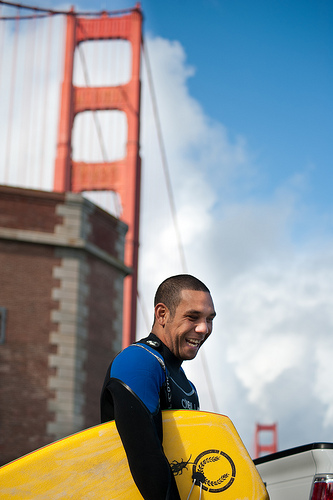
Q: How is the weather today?
A: It is clear.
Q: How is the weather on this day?
A: It is clear.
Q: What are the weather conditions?
A: It is clear.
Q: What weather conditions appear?
A: It is clear.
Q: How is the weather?
A: It is clear.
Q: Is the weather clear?
A: Yes, it is clear.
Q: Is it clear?
A: Yes, it is clear.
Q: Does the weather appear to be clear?
A: Yes, it is clear.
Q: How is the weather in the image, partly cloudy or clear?
A: It is clear.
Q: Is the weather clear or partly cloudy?
A: It is clear.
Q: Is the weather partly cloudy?
A: No, it is clear.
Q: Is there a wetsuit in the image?
A: Yes, there is a wetsuit.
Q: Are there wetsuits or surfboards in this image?
A: Yes, there is a wetsuit.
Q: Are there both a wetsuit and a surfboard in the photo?
A: Yes, there are both a wetsuit and a surfboard.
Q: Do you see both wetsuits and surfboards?
A: Yes, there are both a wetsuit and a surfboard.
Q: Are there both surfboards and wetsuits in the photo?
A: Yes, there are both a wetsuit and a surfboard.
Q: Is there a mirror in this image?
A: No, there are no mirrors.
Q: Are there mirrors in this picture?
A: No, there are no mirrors.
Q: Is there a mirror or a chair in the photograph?
A: No, there are no mirrors or chairs.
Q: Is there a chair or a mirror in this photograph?
A: No, there are no mirrors or chairs.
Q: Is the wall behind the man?
A: Yes, the wall is behind the man.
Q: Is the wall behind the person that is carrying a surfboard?
A: Yes, the wall is behind the man.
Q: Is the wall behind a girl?
A: No, the wall is behind the man.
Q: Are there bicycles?
A: No, there are no bicycles.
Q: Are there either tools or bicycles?
A: No, there are no bicycles or tools.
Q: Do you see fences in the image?
A: No, there are no fences.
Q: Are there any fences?
A: No, there are no fences.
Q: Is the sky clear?
A: Yes, the sky is clear.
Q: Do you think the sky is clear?
A: Yes, the sky is clear.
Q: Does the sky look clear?
A: Yes, the sky is clear.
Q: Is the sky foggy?
A: No, the sky is clear.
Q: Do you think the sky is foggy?
A: No, the sky is clear.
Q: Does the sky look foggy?
A: No, the sky is clear.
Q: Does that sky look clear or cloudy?
A: The sky is clear.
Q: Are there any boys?
A: No, there are no boys.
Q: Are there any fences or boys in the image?
A: No, there are no boys or fences.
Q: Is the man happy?
A: Yes, the man is happy.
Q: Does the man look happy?
A: Yes, the man is happy.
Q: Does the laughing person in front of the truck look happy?
A: Yes, the man is happy.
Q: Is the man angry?
A: No, the man is happy.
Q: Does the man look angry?
A: No, the man is happy.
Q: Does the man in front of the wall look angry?
A: No, the man is happy.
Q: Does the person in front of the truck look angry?
A: No, the man is happy.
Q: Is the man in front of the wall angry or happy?
A: The man is happy.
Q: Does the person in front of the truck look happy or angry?
A: The man is happy.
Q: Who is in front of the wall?
A: The man is in front of the wall.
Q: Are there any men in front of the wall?
A: Yes, there is a man in front of the wall.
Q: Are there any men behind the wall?
A: No, the man is in front of the wall.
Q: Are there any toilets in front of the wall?
A: No, there is a man in front of the wall.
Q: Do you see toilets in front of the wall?
A: No, there is a man in front of the wall.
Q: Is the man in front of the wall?
A: Yes, the man is in front of the wall.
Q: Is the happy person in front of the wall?
A: Yes, the man is in front of the wall.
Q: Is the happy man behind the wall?
A: No, the man is in front of the wall.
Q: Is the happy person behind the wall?
A: No, the man is in front of the wall.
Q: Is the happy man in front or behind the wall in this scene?
A: The man is in front of the wall.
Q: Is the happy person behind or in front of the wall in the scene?
A: The man is in front of the wall.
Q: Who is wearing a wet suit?
A: The man is wearing a wet suit.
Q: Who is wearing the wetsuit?
A: The man is wearing a wet suit.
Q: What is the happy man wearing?
A: The man is wearing a wetsuit.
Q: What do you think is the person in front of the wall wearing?
A: The man is wearing a wetsuit.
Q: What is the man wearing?
A: The man is wearing a wetsuit.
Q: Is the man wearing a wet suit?
A: Yes, the man is wearing a wet suit.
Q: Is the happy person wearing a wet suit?
A: Yes, the man is wearing a wet suit.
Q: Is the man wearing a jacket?
A: No, the man is wearing a wet suit.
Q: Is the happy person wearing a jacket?
A: No, the man is wearing a wet suit.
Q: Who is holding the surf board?
A: The man is holding the surf board.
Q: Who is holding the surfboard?
A: The man is holding the surf board.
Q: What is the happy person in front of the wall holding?
A: The man is holding the surfboard.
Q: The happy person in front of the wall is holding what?
A: The man is holding the surfboard.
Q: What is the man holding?
A: The man is holding the surfboard.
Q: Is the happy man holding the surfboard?
A: Yes, the man is holding the surfboard.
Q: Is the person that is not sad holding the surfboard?
A: Yes, the man is holding the surfboard.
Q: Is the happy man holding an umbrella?
A: No, the man is holding the surfboard.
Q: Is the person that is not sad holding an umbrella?
A: No, the man is holding the surfboard.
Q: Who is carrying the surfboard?
A: The man is carrying the surfboard.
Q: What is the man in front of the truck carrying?
A: The man is carrying a surf board.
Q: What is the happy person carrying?
A: The man is carrying a surf board.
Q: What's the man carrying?
A: The man is carrying a surf board.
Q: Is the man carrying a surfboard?
A: Yes, the man is carrying a surfboard.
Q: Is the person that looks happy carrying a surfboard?
A: Yes, the man is carrying a surfboard.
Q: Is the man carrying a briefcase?
A: No, the man is carrying a surfboard.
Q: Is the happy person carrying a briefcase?
A: No, the man is carrying a surfboard.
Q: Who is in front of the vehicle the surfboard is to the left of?
A: The man is in front of the truck.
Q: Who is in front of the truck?
A: The man is in front of the truck.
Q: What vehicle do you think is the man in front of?
A: The man is in front of the truck.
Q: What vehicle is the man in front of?
A: The man is in front of the truck.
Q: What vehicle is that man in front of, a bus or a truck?
A: The man is in front of a truck.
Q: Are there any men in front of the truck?
A: Yes, there is a man in front of the truck.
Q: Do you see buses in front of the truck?
A: No, there is a man in front of the truck.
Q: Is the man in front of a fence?
A: No, the man is in front of the truck.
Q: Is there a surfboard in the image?
A: Yes, there is a surfboard.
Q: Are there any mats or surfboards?
A: Yes, there is a surfboard.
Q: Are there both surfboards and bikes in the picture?
A: No, there is a surfboard but no bikes.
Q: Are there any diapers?
A: No, there are no diapers.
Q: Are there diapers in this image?
A: No, there are no diapers.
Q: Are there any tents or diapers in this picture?
A: No, there are no diapers or tents.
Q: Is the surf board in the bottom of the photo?
A: Yes, the surf board is in the bottom of the image.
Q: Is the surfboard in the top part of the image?
A: No, the surfboard is in the bottom of the image.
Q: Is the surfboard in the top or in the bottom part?
A: The surfboard is in the bottom of the image.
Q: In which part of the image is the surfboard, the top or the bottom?
A: The surfboard is in the bottom of the image.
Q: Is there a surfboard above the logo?
A: Yes, there is a surfboard above the logo.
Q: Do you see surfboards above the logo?
A: Yes, there is a surfboard above the logo.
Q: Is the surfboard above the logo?
A: Yes, the surfboard is above the logo.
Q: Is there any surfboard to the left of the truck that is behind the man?
A: Yes, there is a surfboard to the left of the truck.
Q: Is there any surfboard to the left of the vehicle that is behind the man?
A: Yes, there is a surfboard to the left of the truck.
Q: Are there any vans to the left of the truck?
A: No, there is a surfboard to the left of the truck.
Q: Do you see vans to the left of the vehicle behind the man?
A: No, there is a surfboard to the left of the truck.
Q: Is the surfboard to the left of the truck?
A: Yes, the surfboard is to the left of the truck.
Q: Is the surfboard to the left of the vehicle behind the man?
A: Yes, the surfboard is to the left of the truck.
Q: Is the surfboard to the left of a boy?
A: No, the surfboard is to the left of the truck.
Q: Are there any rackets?
A: No, there are no rackets.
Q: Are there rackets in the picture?
A: No, there are no rackets.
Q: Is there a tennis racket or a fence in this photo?
A: No, there are no rackets or fences.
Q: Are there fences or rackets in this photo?
A: No, there are no rackets or fences.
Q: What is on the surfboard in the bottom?
A: The logo is on the surfboard.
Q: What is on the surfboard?
A: The logo is on the surfboard.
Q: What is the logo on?
A: The logo is on the surf board.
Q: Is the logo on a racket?
A: No, the logo is on a surfboard.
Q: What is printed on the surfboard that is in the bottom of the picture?
A: The logo is printed on the surfboard.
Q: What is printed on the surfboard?
A: The logo is printed on the surfboard.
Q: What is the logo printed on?
A: The logo is printed on the surfboard.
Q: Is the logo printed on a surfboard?
A: Yes, the logo is printed on a surfboard.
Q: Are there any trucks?
A: Yes, there is a truck.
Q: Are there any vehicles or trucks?
A: Yes, there is a truck.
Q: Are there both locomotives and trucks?
A: No, there is a truck but no locomotives.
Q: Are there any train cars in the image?
A: No, there are no train cars.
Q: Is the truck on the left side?
A: No, the truck is on the right of the image.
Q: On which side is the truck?
A: The truck is on the right of the image.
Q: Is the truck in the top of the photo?
A: No, the truck is in the bottom of the image.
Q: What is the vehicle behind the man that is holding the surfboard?
A: The vehicle is a truck.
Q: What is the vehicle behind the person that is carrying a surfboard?
A: The vehicle is a truck.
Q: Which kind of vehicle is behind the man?
A: The vehicle is a truck.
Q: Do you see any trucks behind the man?
A: Yes, there is a truck behind the man.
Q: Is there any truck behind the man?
A: Yes, there is a truck behind the man.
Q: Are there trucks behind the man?
A: Yes, there is a truck behind the man.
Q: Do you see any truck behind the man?
A: Yes, there is a truck behind the man.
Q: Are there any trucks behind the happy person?
A: Yes, there is a truck behind the man.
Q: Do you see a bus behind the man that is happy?
A: No, there is a truck behind the man.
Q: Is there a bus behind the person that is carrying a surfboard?
A: No, there is a truck behind the man.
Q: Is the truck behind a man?
A: Yes, the truck is behind a man.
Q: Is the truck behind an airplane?
A: No, the truck is behind a man.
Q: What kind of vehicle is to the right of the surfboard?
A: The vehicle is a truck.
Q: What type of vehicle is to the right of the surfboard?
A: The vehicle is a truck.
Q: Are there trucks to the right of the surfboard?
A: Yes, there is a truck to the right of the surfboard.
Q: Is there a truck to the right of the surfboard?
A: Yes, there is a truck to the right of the surfboard.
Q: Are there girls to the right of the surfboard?
A: No, there is a truck to the right of the surfboard.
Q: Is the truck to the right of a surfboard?
A: Yes, the truck is to the right of a surfboard.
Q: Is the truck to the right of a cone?
A: No, the truck is to the right of a surfboard.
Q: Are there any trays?
A: No, there are no trays.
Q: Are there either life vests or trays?
A: No, there are no trays or life vests.